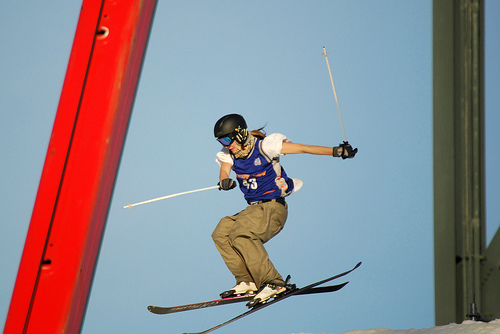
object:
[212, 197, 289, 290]
trousers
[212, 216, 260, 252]
knees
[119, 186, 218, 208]
pole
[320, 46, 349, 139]
pole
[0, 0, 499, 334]
house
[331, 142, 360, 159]
hand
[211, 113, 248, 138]
helmet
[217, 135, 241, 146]
goggles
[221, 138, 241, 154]
face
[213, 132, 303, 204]
shirt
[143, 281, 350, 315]
skis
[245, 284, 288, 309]
feet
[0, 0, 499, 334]
air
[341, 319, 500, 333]
snow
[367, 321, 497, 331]
ground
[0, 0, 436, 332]
sky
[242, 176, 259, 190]
numbers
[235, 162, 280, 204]
stomach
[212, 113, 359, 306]
person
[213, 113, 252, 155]
head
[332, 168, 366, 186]
bad sentence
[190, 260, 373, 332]
ski